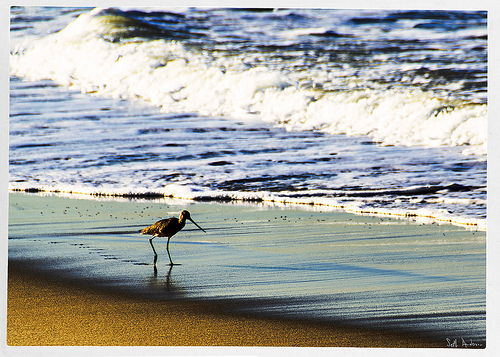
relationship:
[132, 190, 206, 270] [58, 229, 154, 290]
bird left footprints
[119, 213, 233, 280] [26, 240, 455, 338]
bird walking on beach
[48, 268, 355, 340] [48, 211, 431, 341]
sand along shoreline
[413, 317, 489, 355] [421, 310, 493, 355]
signature in right corner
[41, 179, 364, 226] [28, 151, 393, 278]
pebbles scattered on ground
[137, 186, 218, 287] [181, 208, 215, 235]
bird has beak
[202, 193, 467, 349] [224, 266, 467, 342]
ground wet from previous waves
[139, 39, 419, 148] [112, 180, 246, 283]
wave about to crash bird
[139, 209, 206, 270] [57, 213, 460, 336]
bird on beach